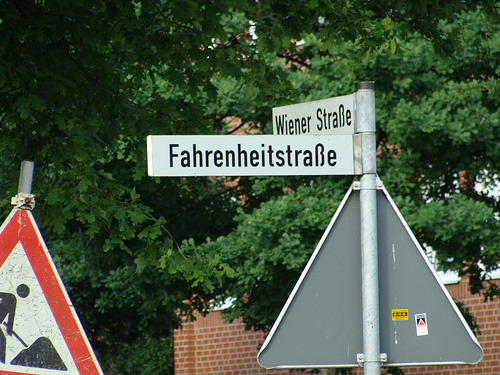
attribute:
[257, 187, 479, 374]
sign — gray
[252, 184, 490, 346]
sign — triangle shaped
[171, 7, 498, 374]
wall — red, brick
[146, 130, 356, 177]
sign — on street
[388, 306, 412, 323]
sticker — yellow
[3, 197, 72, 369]
sign — on street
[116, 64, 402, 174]
signs — grey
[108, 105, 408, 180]
sign — on street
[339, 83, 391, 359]
pole — on street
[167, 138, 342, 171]
name — on street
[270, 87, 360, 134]
street sign — white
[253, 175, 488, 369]
sign — on street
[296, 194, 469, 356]
sign — gray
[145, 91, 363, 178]
signs — white, black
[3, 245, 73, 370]
person — on street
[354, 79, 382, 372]
pole — silver